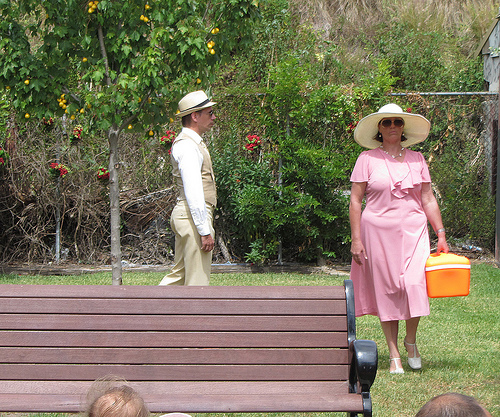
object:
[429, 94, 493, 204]
chain fence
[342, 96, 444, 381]
woman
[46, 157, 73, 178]
flowers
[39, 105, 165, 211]
bushes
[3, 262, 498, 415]
grass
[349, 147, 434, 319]
dress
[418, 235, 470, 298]
container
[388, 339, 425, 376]
shoes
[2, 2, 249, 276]
tree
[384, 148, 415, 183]
bead necklace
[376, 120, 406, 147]
head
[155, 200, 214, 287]
pants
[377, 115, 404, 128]
sunglasses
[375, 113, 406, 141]
face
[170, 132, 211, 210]
shirt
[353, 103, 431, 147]
brim hat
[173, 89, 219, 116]
fedora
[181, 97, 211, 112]
stripe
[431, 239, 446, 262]
handle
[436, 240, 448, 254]
hand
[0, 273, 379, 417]
bench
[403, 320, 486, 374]
grass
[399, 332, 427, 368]
shoe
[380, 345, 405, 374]
shoe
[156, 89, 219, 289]
man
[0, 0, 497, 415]
park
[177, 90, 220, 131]
head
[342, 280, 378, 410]
arm rest